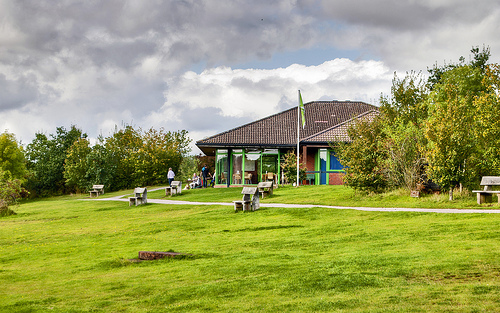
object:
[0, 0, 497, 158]
cloud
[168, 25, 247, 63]
part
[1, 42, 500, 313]
field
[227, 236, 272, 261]
part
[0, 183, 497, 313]
grass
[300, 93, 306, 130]
flag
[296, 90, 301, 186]
flag pole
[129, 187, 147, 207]
seat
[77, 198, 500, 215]
walk way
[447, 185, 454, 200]
tree trunk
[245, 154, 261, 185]
glass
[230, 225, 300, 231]
dark patch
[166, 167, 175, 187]
person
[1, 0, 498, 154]
sky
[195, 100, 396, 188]
building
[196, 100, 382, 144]
roof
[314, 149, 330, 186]
blue entrance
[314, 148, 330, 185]
green border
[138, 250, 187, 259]
slab of cement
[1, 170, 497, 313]
yard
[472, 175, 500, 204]
bench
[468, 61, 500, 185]
tree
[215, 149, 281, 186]
patio porch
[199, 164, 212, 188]
person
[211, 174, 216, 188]
grill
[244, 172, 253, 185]
patio furniture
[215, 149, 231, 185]
green window